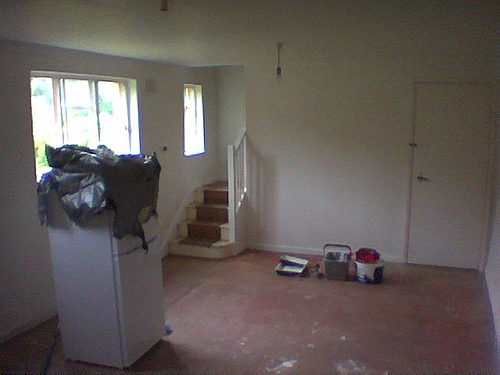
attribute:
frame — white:
[27, 66, 142, 181]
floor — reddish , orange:
[220, 267, 374, 374]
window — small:
[178, 80, 208, 157]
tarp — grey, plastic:
[35, 144, 160, 256]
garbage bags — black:
[33, 142, 158, 222]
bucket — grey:
[321, 242, 351, 282]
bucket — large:
[360, 259, 392, 286]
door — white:
[402, 79, 498, 271]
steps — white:
[169, 176, 243, 268]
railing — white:
[217, 125, 263, 250]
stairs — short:
[172, 170, 239, 257]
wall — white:
[264, 94, 397, 240]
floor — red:
[169, 246, 498, 371]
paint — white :
[232, 344, 397, 371]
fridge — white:
[46, 203, 168, 367]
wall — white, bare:
[247, 4, 499, 276]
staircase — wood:
[169, 128, 252, 260]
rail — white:
[229, 137, 246, 256]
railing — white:
[224, 123, 247, 245]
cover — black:
[40, 144, 173, 215]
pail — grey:
[320, 244, 349, 283]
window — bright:
[31, 76, 134, 178]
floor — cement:
[6, 246, 491, 372]